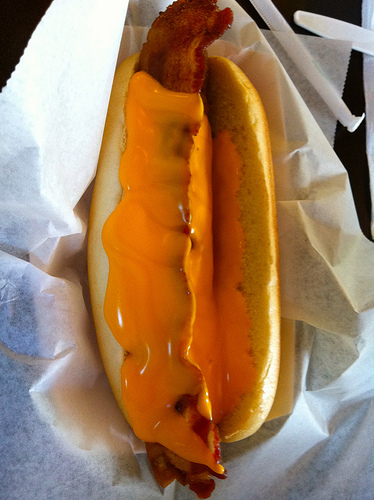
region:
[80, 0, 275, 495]
Hotdog with bacon and cheese topings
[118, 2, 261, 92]
Top of bacon strip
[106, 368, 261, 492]
Bacon strip end covered with cheese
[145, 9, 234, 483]
Edge of a bacon strip covered with cheese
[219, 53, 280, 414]
Hotdog bun covered with cheese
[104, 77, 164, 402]
Cheese dripping onto a hotdog bun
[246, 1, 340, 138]
Straw on a black table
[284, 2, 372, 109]
Plastic knife on a black table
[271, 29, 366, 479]
Crinkled white food paper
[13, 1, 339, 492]
Hotdog with bacon and cheese on a white bun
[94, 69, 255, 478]
bright yellow cheese sauce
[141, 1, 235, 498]
strips of crispy bacon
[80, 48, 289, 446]
toasty yellow bread bun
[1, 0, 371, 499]
transparent white wax paper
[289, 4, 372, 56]
white plastic cutlery handle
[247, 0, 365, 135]
white paper straw wrapper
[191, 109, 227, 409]
cheese covered hot dog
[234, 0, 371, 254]
black table with food on it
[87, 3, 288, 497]
cheese and bacon hot dog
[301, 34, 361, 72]
corner of white wax paper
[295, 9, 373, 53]
White plastic utensil on a table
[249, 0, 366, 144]
Straw in a wrapper on a table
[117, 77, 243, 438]
Melted yellow cheese on a bun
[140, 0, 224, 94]
End of bacon on a bun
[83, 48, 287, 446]
Hot dog bun on white paper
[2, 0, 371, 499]
White paper under a hot dog bun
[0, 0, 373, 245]
Black table under a hot dog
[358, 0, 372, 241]
White napkin on a black table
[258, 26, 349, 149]
Corner of white paper under a straw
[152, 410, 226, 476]
Cheese diagonally on bacon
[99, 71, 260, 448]
cheese on the hot dog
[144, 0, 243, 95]
bacon in the hot dog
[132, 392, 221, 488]
bacon sticking out the other end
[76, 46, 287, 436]
the bun is open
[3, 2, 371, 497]
the paper is white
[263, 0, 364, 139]
a straw on the paper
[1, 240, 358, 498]
the paper is see-through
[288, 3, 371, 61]
a knife on the table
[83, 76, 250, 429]
the cheese is slimy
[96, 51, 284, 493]
the cheese is orange